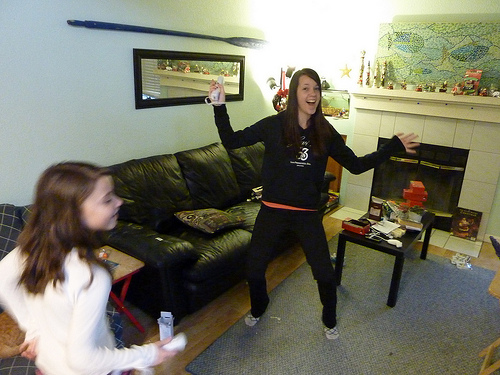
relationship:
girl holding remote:
[204, 67, 421, 342] [208, 75, 225, 106]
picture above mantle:
[370, 18, 499, 96] [348, 81, 499, 128]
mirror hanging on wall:
[134, 46, 248, 112] [0, 2, 324, 208]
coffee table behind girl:
[331, 200, 436, 310] [204, 67, 421, 342]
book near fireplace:
[445, 205, 484, 244] [329, 86, 500, 263]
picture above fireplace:
[370, 18, 499, 96] [329, 86, 500, 263]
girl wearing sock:
[204, 67, 421, 342] [242, 312, 262, 328]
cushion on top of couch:
[172, 206, 247, 234] [94, 141, 335, 326]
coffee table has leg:
[331, 200, 436, 310] [331, 238, 347, 290]